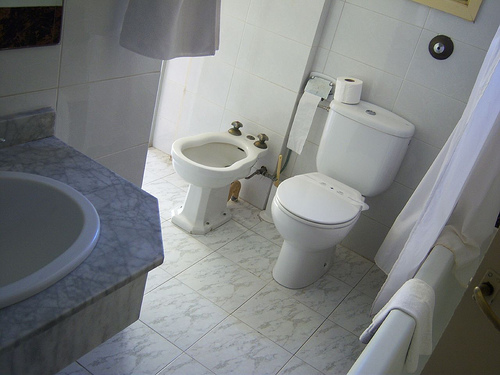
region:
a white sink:
[7, 161, 111, 279]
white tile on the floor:
[176, 250, 315, 365]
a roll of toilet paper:
[332, 73, 357, 104]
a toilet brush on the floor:
[266, 157, 283, 230]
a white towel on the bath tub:
[361, 279, 453, 356]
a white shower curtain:
[368, 32, 498, 302]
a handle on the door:
[474, 286, 489, 312]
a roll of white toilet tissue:
[332, 75, 362, 104]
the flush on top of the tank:
[363, 105, 376, 117]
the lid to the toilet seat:
[275, 173, 364, 225]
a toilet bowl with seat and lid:
[269, 170, 366, 290]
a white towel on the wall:
[116, 2, 221, 59]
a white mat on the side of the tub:
[358, 276, 433, 373]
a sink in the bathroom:
[0, 105, 165, 374]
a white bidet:
[158, 110, 272, 240]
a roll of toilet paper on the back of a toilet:
[330, 71, 365, 111]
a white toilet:
[267, 88, 418, 303]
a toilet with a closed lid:
[269, 84, 414, 298]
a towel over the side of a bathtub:
[340, 272, 447, 373]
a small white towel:
[355, 270, 444, 371]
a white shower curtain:
[365, 13, 497, 338]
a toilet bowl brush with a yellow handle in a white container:
[253, 144, 290, 225]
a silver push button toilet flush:
[359, 105, 379, 120]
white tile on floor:
[154, 294, 205, 331]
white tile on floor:
[160, 189, 189, 217]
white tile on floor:
[156, 159, 188, 191]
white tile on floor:
[332, 269, 364, 309]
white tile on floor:
[293, 317, 348, 374]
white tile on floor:
[128, 335, 148, 361]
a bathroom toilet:
[244, 57, 476, 265]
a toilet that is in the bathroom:
[308, 91, 480, 341]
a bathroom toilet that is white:
[257, 80, 454, 368]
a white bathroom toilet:
[267, 71, 413, 307]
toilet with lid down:
[278, 103, 375, 275]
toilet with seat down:
[284, 98, 394, 278]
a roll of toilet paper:
[305, 51, 421, 136]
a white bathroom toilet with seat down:
[276, 65, 465, 365]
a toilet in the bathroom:
[263, 168, 350, 250]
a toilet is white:
[277, 150, 349, 255]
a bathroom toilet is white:
[261, 133, 371, 260]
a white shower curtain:
[409, 104, 498, 226]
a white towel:
[352, 274, 469, 358]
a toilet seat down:
[282, 171, 346, 258]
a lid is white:
[279, 164, 341, 241]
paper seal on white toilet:
[269, 169, 371, 238]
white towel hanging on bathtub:
[357, 264, 452, 372]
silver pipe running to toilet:
[249, 162, 316, 198]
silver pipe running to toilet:
[219, 123, 284, 192]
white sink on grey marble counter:
[2, 104, 166, 296]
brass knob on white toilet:
[251, 132, 271, 162]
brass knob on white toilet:
[221, 117, 246, 144]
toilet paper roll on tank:
[325, 73, 407, 148]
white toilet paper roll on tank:
[329, 77, 376, 119]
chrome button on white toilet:
[357, 102, 382, 129]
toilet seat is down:
[297, 162, 344, 219]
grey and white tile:
[177, 250, 288, 335]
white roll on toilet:
[342, 71, 364, 107]